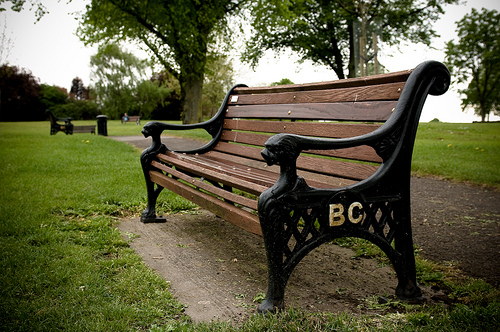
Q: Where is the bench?
A: In the park.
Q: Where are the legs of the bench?
A: In cement.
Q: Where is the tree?
A: Behind the bench.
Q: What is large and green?
A: Tree.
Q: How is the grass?
A: Green.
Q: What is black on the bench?
A: The metal.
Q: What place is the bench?
A: Park.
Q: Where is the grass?
A: In a field.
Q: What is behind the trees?
A: Sky.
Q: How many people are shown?
A: None.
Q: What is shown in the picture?
A: A bench.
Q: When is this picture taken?
A: Daytime.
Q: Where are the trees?
A: Behind the bench.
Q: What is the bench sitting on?
A: Cement.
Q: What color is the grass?
A: Green.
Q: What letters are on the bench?
A: B and C.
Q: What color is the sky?
A: White.